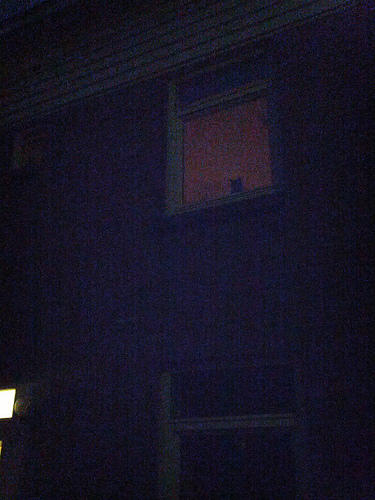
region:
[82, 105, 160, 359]
this is a building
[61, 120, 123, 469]
the building is tall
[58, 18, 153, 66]
this is the roof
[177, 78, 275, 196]
this is a window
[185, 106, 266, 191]
the window is clear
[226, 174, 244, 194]
this is a cat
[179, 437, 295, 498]
this is a door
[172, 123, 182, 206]
the window pane is white in color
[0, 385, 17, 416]
this is some light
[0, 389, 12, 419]
the light is bright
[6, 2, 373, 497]
Scene is in night time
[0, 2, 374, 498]
Picture is black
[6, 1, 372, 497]
A building in the picture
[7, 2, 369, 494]
Building is two stories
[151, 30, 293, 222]
Window in second floor has light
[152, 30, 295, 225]
Window frame is white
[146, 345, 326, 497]
Window has lights turn-off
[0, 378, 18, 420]
Bright light in a window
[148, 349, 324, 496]
Window has white frame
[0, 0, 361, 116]
Roof of home is black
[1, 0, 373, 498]
The shot is dark and grainy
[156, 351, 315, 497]
darkened doorway at the bottom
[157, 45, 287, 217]
The window has a light on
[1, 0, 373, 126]
siding is above the window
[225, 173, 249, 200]
Cats head is in the window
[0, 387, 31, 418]
The light is on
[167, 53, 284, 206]
The blinds are up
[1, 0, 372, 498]
The scene is at night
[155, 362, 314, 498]
The door frame has framed section above it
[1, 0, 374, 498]
The house is large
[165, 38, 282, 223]
a window with a dim light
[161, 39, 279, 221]
a window with two panes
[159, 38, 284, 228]
two panes of different sizes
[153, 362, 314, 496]
the lower window on the wall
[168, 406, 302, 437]
the cross member of the window frame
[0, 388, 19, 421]
a bright light on the left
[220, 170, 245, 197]
a drawing at the bottom of the window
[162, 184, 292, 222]
the window sill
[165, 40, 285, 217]
a white window frame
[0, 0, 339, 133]
shingles from the roof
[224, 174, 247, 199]
One cat is seen.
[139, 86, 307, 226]
cat is sitting near the window.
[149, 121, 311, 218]
windows are white color.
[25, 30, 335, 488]
Night time picture.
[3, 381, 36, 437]
Lights are on.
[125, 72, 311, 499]
Two windows are seen.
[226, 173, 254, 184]
Cat has two small ears.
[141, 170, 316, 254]
Windows are attached to building wall.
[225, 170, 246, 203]
Cat is seeing out through window.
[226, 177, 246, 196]
cat is black color.